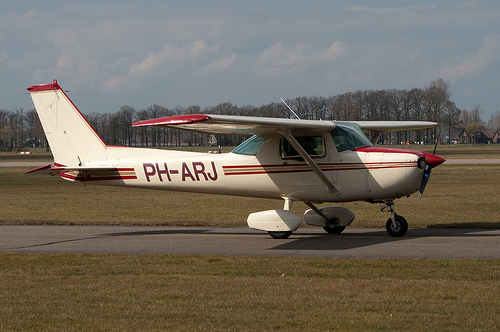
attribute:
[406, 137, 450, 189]
propeller — red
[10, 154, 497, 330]
grass — brownish green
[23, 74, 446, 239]
airplane — white, red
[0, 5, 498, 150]
sky — blue, cloudy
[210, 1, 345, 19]
sky — blue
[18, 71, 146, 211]
tail — white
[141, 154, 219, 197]
letters — red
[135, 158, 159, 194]
letter — P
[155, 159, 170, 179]
letter — H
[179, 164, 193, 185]
letter — A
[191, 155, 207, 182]
letter — R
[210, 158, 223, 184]
letter — J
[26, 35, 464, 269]
plane — white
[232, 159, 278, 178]
stripe — red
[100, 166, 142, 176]
stripe — gold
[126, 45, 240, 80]
clouds — white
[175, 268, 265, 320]
grass — brown